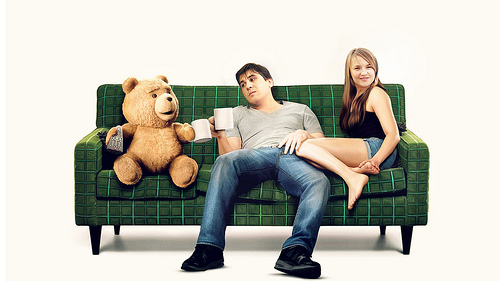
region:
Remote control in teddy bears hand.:
[99, 117, 131, 164]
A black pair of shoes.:
[149, 236, 345, 278]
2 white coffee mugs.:
[176, 104, 241, 168]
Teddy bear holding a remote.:
[96, 65, 199, 193]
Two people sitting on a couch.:
[196, 34, 466, 276]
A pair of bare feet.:
[318, 153, 400, 225]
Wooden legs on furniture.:
[73, 194, 143, 264]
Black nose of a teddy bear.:
[154, 91, 181, 108]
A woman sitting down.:
[320, 35, 417, 265]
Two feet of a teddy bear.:
[90, 151, 206, 221]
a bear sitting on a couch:
[100, 71, 210, 196]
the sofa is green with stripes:
[72, 80, 427, 226]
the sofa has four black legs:
[87, 221, 412, 252]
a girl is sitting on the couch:
[300, 46, 397, 211]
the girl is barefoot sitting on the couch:
[337, 158, 378, 209]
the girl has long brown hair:
[337, 46, 378, 127]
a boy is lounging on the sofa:
[182, 63, 327, 278]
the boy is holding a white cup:
[210, 61, 275, 136]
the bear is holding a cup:
[125, 75, 212, 146]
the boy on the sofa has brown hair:
[233, 58, 277, 106]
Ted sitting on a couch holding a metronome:
[102, 79, 231, 196]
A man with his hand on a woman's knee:
[281, 120, 368, 171]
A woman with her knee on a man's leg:
[283, 127, 370, 187]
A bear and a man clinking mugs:
[173, 97, 261, 147]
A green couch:
[64, 131, 184, 229]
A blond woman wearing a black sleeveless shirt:
[334, 46, 407, 167]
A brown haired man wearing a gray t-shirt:
[211, 56, 330, 162]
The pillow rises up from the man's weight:
[189, 156, 254, 203]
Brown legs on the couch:
[77, 215, 131, 256]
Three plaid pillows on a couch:
[153, 152, 363, 204]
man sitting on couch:
[194, 60, 331, 280]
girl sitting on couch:
[306, 40, 433, 237]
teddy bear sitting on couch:
[95, 64, 210, 209]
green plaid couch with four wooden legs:
[54, 48, 455, 278]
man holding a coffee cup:
[206, 72, 288, 168]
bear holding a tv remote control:
[95, 89, 164, 178]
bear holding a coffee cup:
[131, 77, 224, 164]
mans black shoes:
[158, 200, 393, 277]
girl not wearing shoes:
[307, 24, 405, 232]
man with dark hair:
[171, 56, 305, 129]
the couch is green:
[69, 60, 448, 278]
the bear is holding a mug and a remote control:
[92, 71, 222, 196]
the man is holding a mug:
[178, 64, 340, 279]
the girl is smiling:
[297, 47, 413, 214]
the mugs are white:
[176, 99, 246, 159]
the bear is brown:
[89, 65, 206, 196]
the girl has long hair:
[316, 30, 400, 155]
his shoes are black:
[171, 207, 333, 279]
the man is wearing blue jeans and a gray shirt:
[181, 57, 339, 279]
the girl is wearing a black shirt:
[327, 41, 412, 207]